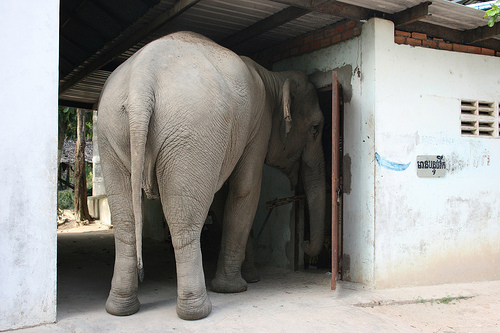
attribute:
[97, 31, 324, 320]
elephant — large, gray, wrinkly, looking, inside building, smiling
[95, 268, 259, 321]
feet — round, wide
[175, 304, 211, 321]
foot — round, wide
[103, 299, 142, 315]
foot — round, wide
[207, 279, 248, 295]
foot — round, wide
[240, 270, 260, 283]
foot — round, wide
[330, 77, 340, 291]
door — red, open, metal, faded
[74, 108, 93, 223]
tree — tall, brown, dead, long, in background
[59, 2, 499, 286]
building — white, in shambles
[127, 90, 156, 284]
tail — long, gray, hairless, wrinkly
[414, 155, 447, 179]
sign — white, gray, black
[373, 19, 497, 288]
wall — white, cement, dirty, old, plastered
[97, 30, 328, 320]
skin — wrinkled, hairless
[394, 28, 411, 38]
brick — red, rectangle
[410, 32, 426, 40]
brick — red, rectangle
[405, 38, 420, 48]
brick — red, rectangle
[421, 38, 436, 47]
brick — red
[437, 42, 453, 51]
brick — red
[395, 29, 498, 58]
bricks — dark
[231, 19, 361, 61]
bricks — dark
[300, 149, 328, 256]
trunk — long, gray, wrinkly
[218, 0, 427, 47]
frame — wooden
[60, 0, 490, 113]
ceiling — sheet metal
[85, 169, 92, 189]
grass — green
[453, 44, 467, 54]
brick — rectangular, red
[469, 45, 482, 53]
brick — rectangular, red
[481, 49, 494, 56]
brick — rectangular, red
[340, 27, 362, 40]
brick — rectangular, red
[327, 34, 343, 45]
brick — rectangular, red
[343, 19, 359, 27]
brick — red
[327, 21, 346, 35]
brick — rectangle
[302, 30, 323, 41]
brick — rectangle, red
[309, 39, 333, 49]
brick — rectangle, red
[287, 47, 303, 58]
brick — rectangle, red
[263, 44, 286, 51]
brick — rectangle, red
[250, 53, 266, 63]
brick — rectangle, red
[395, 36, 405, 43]
brick — rectangle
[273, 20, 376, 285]
wall — old, plastered, dirty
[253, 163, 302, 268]
wall — old, plastered, dirty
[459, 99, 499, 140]
vents — slatted, white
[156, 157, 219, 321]
leg — long, wrinkly, gray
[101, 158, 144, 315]
leg — long, wrinkly, gray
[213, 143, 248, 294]
leg — long, wrinkly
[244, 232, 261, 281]
leg — long, wrinkly, gray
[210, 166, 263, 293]
leg — long, gray, wrinkly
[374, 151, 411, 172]
paint — blue, a swoosh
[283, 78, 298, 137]
ear — wrinkly, gray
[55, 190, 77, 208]
weeds — growing